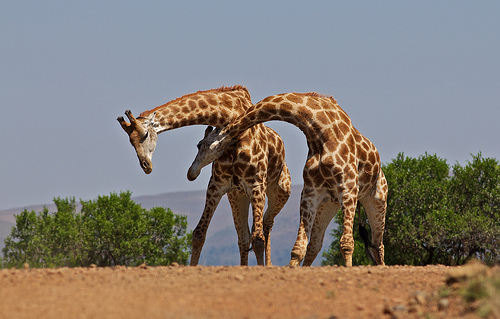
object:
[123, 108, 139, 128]
horns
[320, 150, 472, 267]
tree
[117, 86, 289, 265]
giraffe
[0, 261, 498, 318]
dirt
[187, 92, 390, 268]
giraffe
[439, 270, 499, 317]
grass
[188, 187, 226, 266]
legs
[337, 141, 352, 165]
spots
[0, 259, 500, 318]
ground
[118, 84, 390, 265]
two giraffe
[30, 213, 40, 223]
green/tree leaves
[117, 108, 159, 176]
giraffe head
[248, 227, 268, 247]
knee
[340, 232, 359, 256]
knee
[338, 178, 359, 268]
legs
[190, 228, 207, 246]
knee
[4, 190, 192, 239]
tree tops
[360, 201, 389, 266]
legs